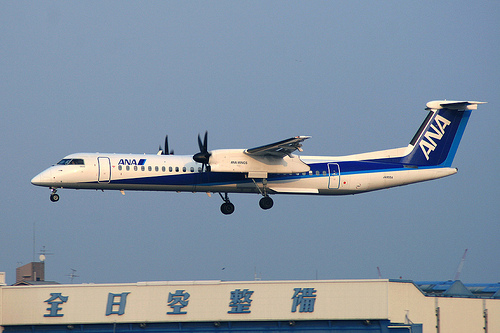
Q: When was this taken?
A: During the day.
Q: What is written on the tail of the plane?
A: ANA.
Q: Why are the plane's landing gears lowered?
A: The plane is about to land.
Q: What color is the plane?
A: Blue and white.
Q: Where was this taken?
A: At an airport.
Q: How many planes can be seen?
A: One.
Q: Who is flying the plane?
A: A pilot.